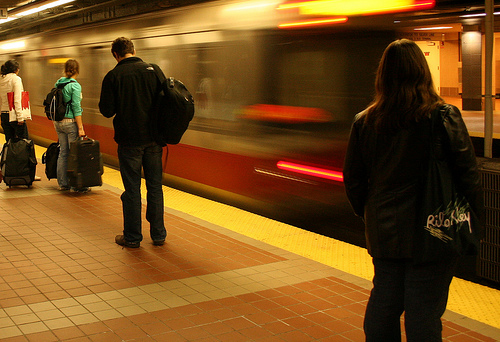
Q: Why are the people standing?
A: They are waiting to get on the train.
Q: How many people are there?
A: Four.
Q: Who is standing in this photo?
A: Men and women.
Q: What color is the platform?
A: Yellow and red.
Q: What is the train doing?
A: Moving.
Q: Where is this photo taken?
A: At a train station.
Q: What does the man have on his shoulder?
A: A backpack.